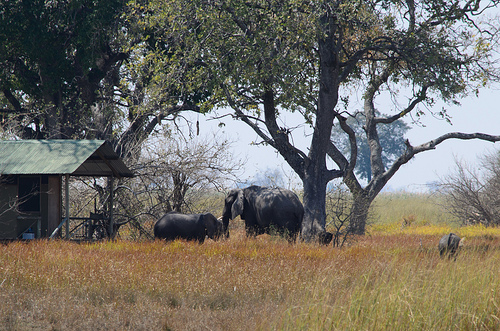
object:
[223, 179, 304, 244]
elephant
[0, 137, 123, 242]
house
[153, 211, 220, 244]
elephant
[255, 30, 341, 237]
tree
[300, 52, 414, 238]
tree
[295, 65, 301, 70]
leaves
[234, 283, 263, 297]
grass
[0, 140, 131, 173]
roof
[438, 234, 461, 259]
elephant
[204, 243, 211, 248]
flowers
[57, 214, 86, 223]
railing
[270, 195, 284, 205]
shadows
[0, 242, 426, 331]
field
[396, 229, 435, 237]
plain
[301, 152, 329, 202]
trunk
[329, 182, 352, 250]
tree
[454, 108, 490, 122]
sky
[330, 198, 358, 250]
bush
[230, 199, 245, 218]
ear